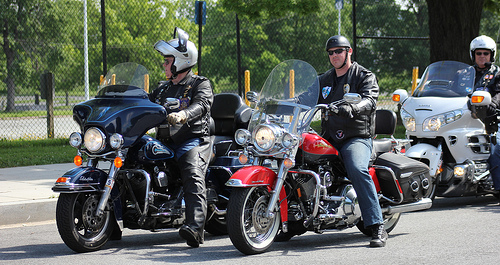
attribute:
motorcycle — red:
[214, 51, 441, 251]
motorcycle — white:
[387, 59, 499, 213]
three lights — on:
[60, 124, 130, 160]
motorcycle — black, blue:
[46, 55, 272, 255]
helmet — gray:
[148, 24, 210, 79]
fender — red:
[217, 162, 301, 234]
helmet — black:
[318, 33, 361, 52]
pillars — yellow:
[91, 62, 426, 99]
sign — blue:
[190, 1, 212, 26]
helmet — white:
[467, 33, 497, 54]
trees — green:
[4, 0, 432, 84]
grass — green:
[4, 132, 83, 168]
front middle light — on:
[250, 121, 280, 154]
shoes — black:
[357, 220, 398, 252]